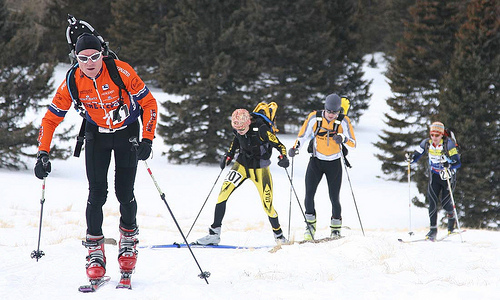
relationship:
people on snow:
[35, 31, 462, 280] [1, 52, 500, 298]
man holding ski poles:
[35, 33, 157, 278] [31, 137, 210, 284]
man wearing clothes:
[35, 33, 157, 278] [35, 55, 157, 236]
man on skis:
[35, 33, 157, 278] [79, 275, 132, 293]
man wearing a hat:
[35, 33, 157, 278] [75, 32, 101, 55]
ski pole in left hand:
[129, 135, 211, 285] [131, 137, 152, 161]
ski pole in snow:
[29, 156, 49, 263] [1, 52, 500, 298]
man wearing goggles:
[35, 33, 157, 278] [74, 49, 103, 64]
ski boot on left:
[83, 234, 107, 279] [85, 234, 106, 279]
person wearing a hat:
[289, 92, 355, 240] [324, 93, 342, 112]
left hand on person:
[333, 133, 345, 145] [289, 92, 355, 240]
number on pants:
[226, 169, 240, 184] [213, 159, 283, 233]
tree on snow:
[0, 0, 85, 170] [1, 52, 500, 298]